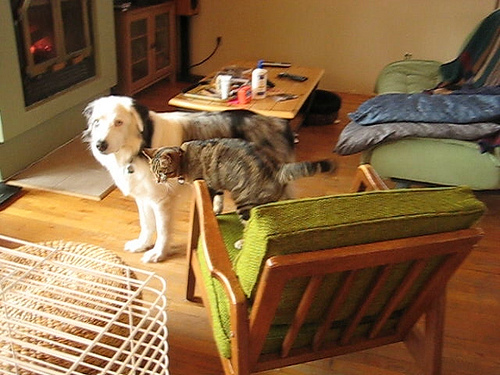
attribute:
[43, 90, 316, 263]
dog — white, black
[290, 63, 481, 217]
pillow — blue